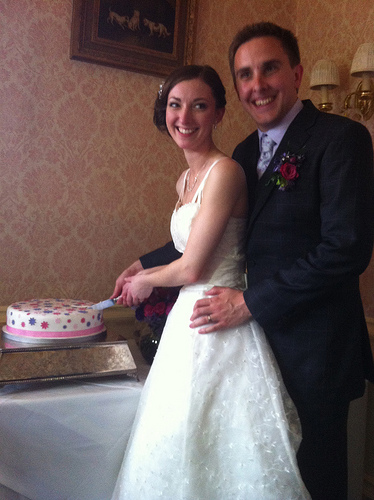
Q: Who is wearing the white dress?
A: Wife.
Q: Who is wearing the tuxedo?
A: Husband.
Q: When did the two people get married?
A: Day of picture.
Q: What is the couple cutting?
A: Cake.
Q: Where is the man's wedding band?
A: Left ring finger.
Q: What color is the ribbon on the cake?
A: Pink.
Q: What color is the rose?
A: Red.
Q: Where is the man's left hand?
A: Bride's hip.